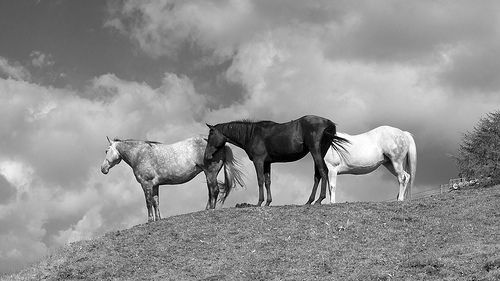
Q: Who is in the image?
A: There are no people in the image.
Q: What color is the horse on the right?
A: White.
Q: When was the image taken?
A: During the day.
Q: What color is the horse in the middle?
A: Black.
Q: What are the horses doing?
A: Standing.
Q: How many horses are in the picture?
A: Three.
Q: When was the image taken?
A: Once the horses lined up.